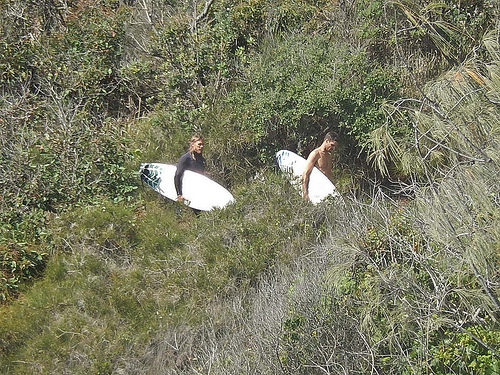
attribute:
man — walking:
[166, 129, 209, 200]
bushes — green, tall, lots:
[7, 9, 496, 375]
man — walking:
[294, 118, 346, 203]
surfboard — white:
[136, 160, 242, 217]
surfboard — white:
[270, 145, 350, 224]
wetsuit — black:
[173, 151, 207, 193]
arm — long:
[171, 158, 195, 207]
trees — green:
[8, 11, 228, 111]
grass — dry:
[153, 302, 320, 373]